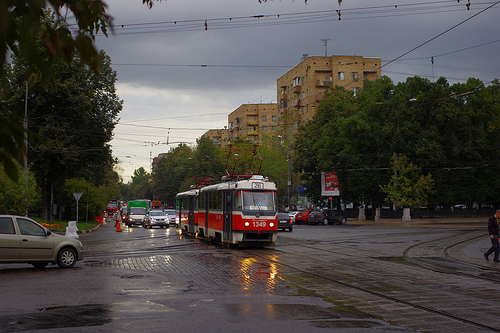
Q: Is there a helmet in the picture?
A: No, there are no helmets.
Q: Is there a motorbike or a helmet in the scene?
A: No, there are no helmets or motorcycles.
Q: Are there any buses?
A: Yes, there is a bus.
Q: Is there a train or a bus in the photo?
A: Yes, there is a bus.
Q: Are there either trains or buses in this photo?
A: Yes, there is a bus.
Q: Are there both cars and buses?
A: Yes, there are both a bus and a car.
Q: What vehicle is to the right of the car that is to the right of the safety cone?
A: The vehicle is a bus.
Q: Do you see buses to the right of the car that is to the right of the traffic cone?
A: Yes, there is a bus to the right of the car.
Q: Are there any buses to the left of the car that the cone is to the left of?
A: No, the bus is to the right of the car.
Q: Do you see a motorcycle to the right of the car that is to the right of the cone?
A: No, there is a bus to the right of the car.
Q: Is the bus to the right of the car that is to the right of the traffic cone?
A: Yes, the bus is to the right of the car.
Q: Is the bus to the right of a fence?
A: No, the bus is to the right of the car.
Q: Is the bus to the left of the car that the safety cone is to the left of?
A: No, the bus is to the right of the car.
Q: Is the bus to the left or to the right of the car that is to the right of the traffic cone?
A: The bus is to the right of the car.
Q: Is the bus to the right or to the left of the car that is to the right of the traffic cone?
A: The bus is to the right of the car.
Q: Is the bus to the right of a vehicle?
A: No, the bus is to the left of a vehicle.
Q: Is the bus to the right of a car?
A: Yes, the bus is to the right of a car.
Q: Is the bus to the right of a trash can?
A: No, the bus is to the right of a car.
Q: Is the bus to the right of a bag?
A: No, the bus is to the right of the vehicle.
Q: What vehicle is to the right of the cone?
A: The vehicle is a bus.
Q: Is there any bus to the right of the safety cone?
A: Yes, there is a bus to the right of the safety cone.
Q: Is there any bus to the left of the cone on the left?
A: No, the bus is to the right of the safety cone.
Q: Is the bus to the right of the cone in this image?
A: Yes, the bus is to the right of the cone.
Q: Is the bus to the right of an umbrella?
A: No, the bus is to the right of the cone.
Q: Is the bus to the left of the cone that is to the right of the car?
A: No, the bus is to the right of the cone.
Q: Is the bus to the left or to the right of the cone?
A: The bus is to the right of the cone.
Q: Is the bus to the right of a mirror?
A: No, the bus is to the right of a car.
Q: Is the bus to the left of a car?
A: No, the bus is to the right of a car.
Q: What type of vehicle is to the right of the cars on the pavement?
A: The vehicle is a bus.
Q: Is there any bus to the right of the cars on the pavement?
A: Yes, there is a bus to the right of the cars.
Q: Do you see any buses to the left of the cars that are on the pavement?
A: No, the bus is to the right of the cars.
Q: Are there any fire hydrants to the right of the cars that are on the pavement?
A: No, there is a bus to the right of the cars.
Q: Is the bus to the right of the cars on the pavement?
A: Yes, the bus is to the right of the cars.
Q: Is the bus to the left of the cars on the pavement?
A: No, the bus is to the right of the cars.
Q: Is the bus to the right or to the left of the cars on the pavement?
A: The bus is to the right of the cars.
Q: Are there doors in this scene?
A: Yes, there is a door.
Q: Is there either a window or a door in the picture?
A: Yes, there is a door.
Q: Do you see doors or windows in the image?
A: Yes, there is a door.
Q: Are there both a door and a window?
A: Yes, there are both a door and a window.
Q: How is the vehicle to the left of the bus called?
A: The vehicle is a car.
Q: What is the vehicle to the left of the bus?
A: The vehicle is a car.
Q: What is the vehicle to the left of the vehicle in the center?
A: The vehicle is a car.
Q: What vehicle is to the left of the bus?
A: The vehicle is a car.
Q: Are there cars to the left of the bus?
A: Yes, there is a car to the left of the bus.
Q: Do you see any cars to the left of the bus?
A: Yes, there is a car to the left of the bus.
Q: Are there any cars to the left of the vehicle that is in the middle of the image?
A: Yes, there is a car to the left of the bus.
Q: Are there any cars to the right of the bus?
A: No, the car is to the left of the bus.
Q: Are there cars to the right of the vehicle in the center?
A: No, the car is to the left of the bus.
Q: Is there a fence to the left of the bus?
A: No, there is a car to the left of the bus.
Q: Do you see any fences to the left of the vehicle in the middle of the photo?
A: No, there is a car to the left of the bus.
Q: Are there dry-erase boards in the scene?
A: No, there are no dry-erase boards.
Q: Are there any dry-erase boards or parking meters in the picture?
A: No, there are no dry-erase boards or parking meters.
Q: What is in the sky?
A: The clouds are in the sky.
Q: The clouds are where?
A: The clouds are in the sky.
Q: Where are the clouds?
A: The clouds are in the sky.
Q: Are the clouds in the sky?
A: Yes, the clouds are in the sky.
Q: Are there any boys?
A: No, there are no boys.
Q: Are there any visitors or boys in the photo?
A: No, there are no boys or visitors.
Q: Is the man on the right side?
A: Yes, the man is on the right of the image.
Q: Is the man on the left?
A: No, the man is on the right of the image.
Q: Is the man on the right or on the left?
A: The man is on the right of the image.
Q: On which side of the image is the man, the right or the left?
A: The man is on the right of the image.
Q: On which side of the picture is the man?
A: The man is on the right of the image.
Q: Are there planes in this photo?
A: No, there are no planes.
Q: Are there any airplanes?
A: No, there are no airplanes.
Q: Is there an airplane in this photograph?
A: No, there are no airplanes.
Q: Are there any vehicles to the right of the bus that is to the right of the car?
A: Yes, there is a vehicle to the right of the bus.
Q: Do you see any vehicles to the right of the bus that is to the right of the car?
A: Yes, there is a vehicle to the right of the bus.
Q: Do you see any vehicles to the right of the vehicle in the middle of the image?
A: Yes, there is a vehicle to the right of the bus.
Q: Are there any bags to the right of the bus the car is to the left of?
A: No, there is a vehicle to the right of the bus.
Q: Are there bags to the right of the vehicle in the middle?
A: No, there is a vehicle to the right of the bus.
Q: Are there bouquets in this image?
A: No, there are no bouquets.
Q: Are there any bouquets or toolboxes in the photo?
A: No, there are no bouquets or toolboxes.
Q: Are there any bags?
A: No, there are no bags.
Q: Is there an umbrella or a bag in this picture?
A: No, there are no bags or umbrellas.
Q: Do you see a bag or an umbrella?
A: No, there are no bags or umbrellas.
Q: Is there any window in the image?
A: Yes, there is a window.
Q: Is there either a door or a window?
A: Yes, there is a window.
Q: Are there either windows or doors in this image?
A: Yes, there is a window.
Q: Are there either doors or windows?
A: Yes, there is a window.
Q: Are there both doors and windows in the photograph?
A: Yes, there are both a window and a door.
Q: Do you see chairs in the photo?
A: No, there are no chairs.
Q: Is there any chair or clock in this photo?
A: No, there are no chairs or clocks.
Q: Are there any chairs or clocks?
A: No, there are no chairs or clocks.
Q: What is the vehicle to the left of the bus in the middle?
A: The vehicle is a car.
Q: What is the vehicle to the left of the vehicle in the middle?
A: The vehicle is a car.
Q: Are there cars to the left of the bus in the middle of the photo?
A: Yes, there is a car to the left of the bus.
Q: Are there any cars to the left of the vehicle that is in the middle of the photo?
A: Yes, there is a car to the left of the bus.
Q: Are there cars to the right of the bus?
A: No, the car is to the left of the bus.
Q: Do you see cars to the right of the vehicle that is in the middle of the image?
A: No, the car is to the left of the bus.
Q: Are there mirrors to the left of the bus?
A: No, there is a car to the left of the bus.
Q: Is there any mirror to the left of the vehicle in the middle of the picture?
A: No, there is a car to the left of the bus.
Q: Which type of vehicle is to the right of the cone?
A: The vehicle is a car.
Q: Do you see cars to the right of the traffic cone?
A: Yes, there is a car to the right of the traffic cone.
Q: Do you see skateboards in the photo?
A: No, there are no skateboards.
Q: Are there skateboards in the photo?
A: No, there are no skateboards.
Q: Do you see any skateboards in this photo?
A: No, there are no skateboards.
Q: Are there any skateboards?
A: No, there are no skateboards.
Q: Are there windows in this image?
A: Yes, there is a window.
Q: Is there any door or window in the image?
A: Yes, there is a window.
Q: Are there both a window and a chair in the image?
A: No, there is a window but no chairs.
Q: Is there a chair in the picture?
A: No, there are no chairs.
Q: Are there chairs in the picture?
A: No, there are no chairs.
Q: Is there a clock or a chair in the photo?
A: No, there are no chairs or clocks.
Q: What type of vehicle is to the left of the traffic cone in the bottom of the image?
A: The vehicle is a car.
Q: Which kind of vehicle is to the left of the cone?
A: The vehicle is a car.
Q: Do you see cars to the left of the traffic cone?
A: Yes, there is a car to the left of the traffic cone.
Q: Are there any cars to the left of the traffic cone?
A: Yes, there is a car to the left of the traffic cone.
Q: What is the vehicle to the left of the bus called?
A: The vehicle is a car.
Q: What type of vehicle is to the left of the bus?
A: The vehicle is a car.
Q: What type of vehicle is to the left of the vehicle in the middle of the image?
A: The vehicle is a car.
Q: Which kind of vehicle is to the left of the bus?
A: The vehicle is a car.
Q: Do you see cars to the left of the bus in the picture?
A: Yes, there is a car to the left of the bus.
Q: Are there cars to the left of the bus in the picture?
A: Yes, there is a car to the left of the bus.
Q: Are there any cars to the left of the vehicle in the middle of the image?
A: Yes, there is a car to the left of the bus.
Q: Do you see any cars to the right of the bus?
A: No, the car is to the left of the bus.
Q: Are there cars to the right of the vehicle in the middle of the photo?
A: No, the car is to the left of the bus.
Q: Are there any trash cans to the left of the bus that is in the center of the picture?
A: No, there is a car to the left of the bus.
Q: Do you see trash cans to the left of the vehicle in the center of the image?
A: No, there is a car to the left of the bus.